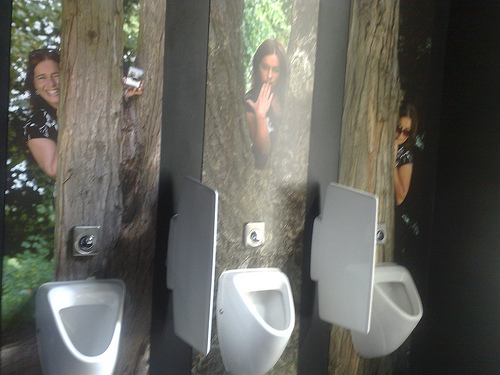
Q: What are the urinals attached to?
A: Trees.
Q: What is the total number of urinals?
A: 3.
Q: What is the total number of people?
A: 3.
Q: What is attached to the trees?
A: Urinals.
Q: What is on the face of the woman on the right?
A: Sunglasses.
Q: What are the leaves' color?
A: Green.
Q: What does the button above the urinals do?
A: Flush them.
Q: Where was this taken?
A: A men's public restroom.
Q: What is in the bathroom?
A: Urinals.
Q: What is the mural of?
A: A woman and trees.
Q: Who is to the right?
A: A woman.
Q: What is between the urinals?
A: White dividers.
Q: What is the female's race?
A: Caucasian.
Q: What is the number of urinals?
A: Three.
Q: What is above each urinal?
A: Flusher.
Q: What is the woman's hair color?
A: Brunette.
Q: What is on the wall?
A: Pictures.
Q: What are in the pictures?
A: Trees.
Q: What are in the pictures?
A: Woman looking at you.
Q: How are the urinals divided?
A: With short walls.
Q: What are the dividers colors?
A: White.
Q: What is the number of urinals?
A: Three.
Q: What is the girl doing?
A: Peeking out from behind the tree.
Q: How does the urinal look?
A: Attached to a tree.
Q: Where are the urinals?
A: Wall.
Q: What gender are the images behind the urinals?
A: Female.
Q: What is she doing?
A: Smiling.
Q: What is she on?
A: A tree.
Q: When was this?
A: Daytime.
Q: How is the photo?
A: Blurry.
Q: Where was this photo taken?
A: In the bathroom.